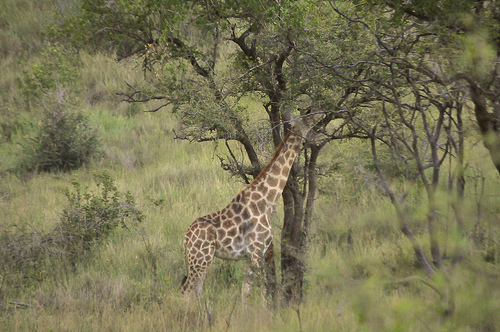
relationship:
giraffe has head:
[180, 102, 333, 316] [297, 98, 330, 126]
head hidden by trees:
[297, 98, 330, 126] [78, 0, 499, 304]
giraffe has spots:
[180, 102, 333, 316] [182, 129, 300, 300]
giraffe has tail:
[180, 102, 333, 316] [178, 238, 190, 291]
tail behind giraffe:
[178, 238, 190, 291] [180, 102, 333, 316]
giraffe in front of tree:
[180, 102, 333, 316] [67, 0, 373, 308]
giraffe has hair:
[180, 102, 333, 316] [244, 126, 295, 186]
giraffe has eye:
[180, 102, 333, 316] [304, 106, 314, 115]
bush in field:
[22, 1, 499, 303] [1, 3, 500, 329]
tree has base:
[67, 0, 373, 308] [255, 168, 317, 304]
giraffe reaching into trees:
[180, 102, 333, 316] [78, 0, 499, 304]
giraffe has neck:
[180, 102, 333, 316] [254, 124, 306, 205]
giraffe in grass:
[180, 102, 333, 316] [3, 9, 489, 329]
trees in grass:
[78, 0, 499, 304] [3, 9, 489, 329]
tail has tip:
[178, 238, 190, 291] [177, 274, 189, 289]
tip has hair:
[177, 274, 189, 289] [179, 275, 189, 287]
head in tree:
[297, 98, 330, 126] [67, 0, 373, 308]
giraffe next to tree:
[180, 102, 333, 316] [67, 0, 373, 308]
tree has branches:
[67, 0, 373, 308] [76, 1, 406, 179]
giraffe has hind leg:
[180, 102, 333, 316] [179, 256, 213, 304]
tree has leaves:
[67, 0, 373, 308] [63, 3, 392, 193]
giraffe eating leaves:
[180, 102, 333, 316] [63, 3, 392, 193]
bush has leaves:
[22, 1, 499, 303] [13, 2, 490, 279]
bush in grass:
[22, 1, 499, 303] [3, 9, 489, 329]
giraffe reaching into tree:
[180, 102, 333, 316] [67, 0, 373, 308]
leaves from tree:
[63, 3, 392, 193] [67, 0, 373, 308]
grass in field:
[3, 9, 489, 329] [1, 3, 500, 329]